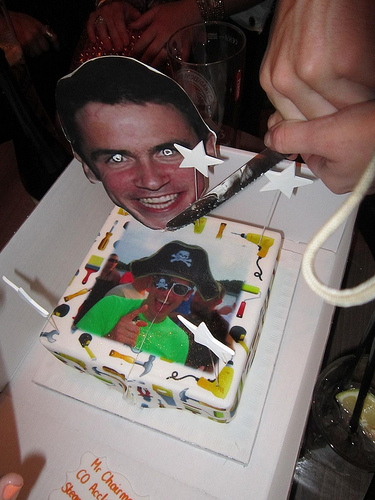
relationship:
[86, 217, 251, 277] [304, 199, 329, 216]
cake on board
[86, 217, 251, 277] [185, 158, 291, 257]
cake has tools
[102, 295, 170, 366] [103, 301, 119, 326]
man in shirt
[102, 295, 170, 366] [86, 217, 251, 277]
man on cake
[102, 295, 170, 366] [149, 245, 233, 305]
man in hat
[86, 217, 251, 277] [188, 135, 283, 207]
cake has stars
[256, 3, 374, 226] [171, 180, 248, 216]
person with knife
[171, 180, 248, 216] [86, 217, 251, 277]
knife for cake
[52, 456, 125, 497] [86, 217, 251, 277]
writing by cake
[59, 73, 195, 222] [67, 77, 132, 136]
cardboard of head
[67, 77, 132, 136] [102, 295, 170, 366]
head of man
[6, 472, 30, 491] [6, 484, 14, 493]
finger with polish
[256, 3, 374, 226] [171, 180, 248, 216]
hands holding knife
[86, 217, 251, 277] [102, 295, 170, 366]
cake with man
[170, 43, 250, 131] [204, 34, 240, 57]
glass for beer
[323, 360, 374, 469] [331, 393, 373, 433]
glass with drink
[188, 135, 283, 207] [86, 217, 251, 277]
stars on cake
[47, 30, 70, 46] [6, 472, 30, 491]
ring on finger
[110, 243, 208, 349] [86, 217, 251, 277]
picture of cake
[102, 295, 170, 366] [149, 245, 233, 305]
man wearing hat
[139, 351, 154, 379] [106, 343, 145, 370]
hammer with handle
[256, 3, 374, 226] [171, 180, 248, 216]
person holding knife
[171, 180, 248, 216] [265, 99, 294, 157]
knife in hands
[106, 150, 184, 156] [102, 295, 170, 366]
eyes of man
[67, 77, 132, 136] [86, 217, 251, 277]
head on cake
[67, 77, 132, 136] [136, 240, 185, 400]
head in photo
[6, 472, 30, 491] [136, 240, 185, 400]
finger in photo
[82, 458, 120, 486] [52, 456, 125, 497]
paper with writing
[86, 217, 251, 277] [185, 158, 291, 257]
cake with tools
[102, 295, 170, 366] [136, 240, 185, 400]
man in photo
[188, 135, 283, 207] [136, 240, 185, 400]
stars in photo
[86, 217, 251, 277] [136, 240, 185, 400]
cake with photo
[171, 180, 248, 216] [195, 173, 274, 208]
knife has frosting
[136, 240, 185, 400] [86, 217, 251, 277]
photo on cake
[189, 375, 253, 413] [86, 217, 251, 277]
drill on cake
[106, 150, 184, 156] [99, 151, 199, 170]
eyes looking demonic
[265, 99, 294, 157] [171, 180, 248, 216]
hands holding knife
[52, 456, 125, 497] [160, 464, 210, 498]
writing on box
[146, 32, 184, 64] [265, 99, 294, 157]
part of hands